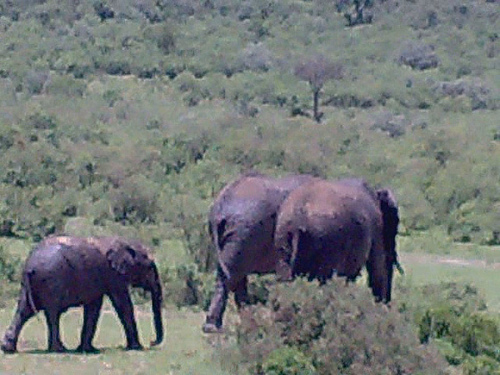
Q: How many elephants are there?
A: Three.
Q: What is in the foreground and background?
A: Shrubs and bushes.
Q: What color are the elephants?
A: A shade of gray.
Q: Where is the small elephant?
A: Trailing the other two.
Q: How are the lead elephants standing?
A: Side by side.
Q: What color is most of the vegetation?
A: Green.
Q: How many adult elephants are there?
A: Two.